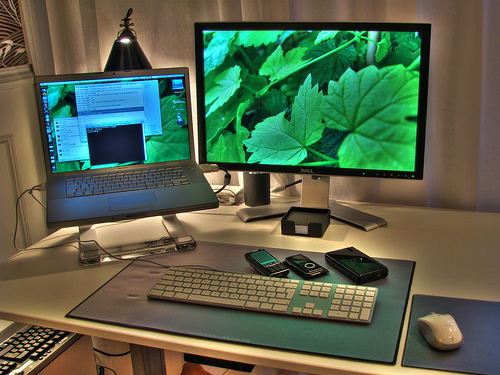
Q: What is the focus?
A: Computer desk.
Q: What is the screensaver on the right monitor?
A: Leaves.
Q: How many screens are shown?
A: 2.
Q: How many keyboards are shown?
A: 3.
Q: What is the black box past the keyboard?
A: Nintendo ds.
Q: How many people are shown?
A: 0.